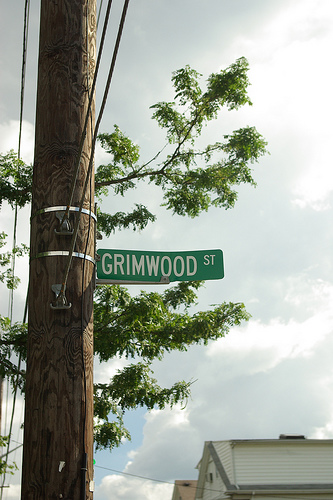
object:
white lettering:
[102, 249, 215, 275]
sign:
[95, 246, 225, 284]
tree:
[3, 70, 271, 467]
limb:
[94, 282, 240, 356]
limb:
[0, 319, 23, 379]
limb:
[93, 362, 193, 445]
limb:
[1, 151, 32, 207]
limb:
[94, 52, 268, 226]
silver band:
[29, 205, 99, 222]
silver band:
[27, 248, 98, 264]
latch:
[49, 282, 71, 310]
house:
[191, 435, 331, 500]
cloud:
[249, 10, 332, 76]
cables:
[52, 2, 128, 311]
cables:
[6, 1, 28, 418]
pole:
[20, 1, 97, 491]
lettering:
[103, 252, 198, 275]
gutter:
[229, 443, 241, 492]